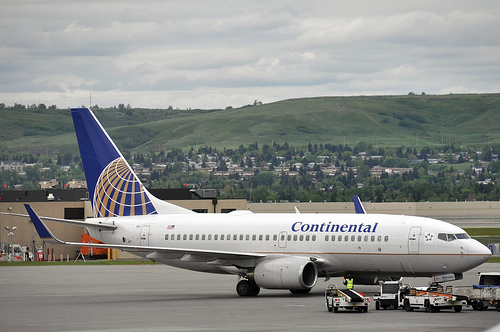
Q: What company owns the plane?
A: Continental.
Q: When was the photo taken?
A: During the day.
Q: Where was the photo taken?
A: At an airport.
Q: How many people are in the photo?
A: One.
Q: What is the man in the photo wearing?
A: A reflective vest.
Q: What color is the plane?
A: White.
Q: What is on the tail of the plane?
A: A sphere.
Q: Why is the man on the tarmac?
A: To direct the plane.